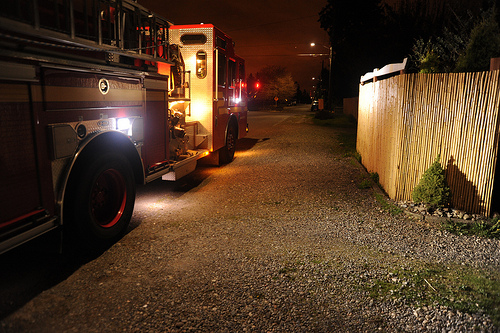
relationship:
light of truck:
[108, 113, 141, 136] [34, 80, 125, 215]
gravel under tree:
[196, 299, 496, 333] [408, 140, 477, 197]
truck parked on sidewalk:
[5, 0, 259, 216] [33, 104, 500, 333]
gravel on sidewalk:
[0, 106, 496, 333] [245, 104, 422, 317]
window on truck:
[197, 51, 212, 84] [4, 79, 258, 265]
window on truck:
[197, 51, 212, 84] [3, 91, 262, 261]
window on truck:
[197, 51, 212, 84] [6, 91, 259, 293]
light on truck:
[108, 113, 141, 136] [6, 91, 259, 293]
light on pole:
[108, 113, 141, 136] [306, 78, 327, 118]